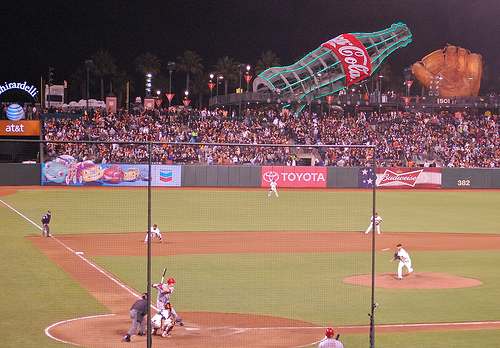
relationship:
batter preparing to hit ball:
[151, 270, 186, 300] [378, 245, 389, 257]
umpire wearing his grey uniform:
[126, 290, 148, 340] [130, 306, 144, 322]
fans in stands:
[87, 116, 123, 144] [114, 130, 229, 172]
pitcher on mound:
[389, 243, 416, 270] [377, 267, 417, 299]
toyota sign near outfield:
[262, 166, 324, 185] [223, 187, 318, 222]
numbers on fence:
[456, 178, 472, 190] [446, 170, 496, 189]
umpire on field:
[126, 290, 148, 340] [206, 269, 256, 299]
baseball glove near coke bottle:
[417, 42, 489, 104] [253, 29, 402, 91]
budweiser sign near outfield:
[364, 167, 442, 187] [223, 187, 318, 222]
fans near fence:
[87, 116, 123, 144] [446, 170, 496, 189]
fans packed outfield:
[87, 116, 123, 144] [223, 187, 318, 222]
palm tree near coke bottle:
[135, 49, 161, 84] [253, 29, 402, 91]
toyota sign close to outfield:
[262, 166, 324, 185] [223, 187, 318, 222]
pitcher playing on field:
[389, 243, 416, 270] [206, 269, 256, 299]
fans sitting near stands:
[87, 116, 123, 144] [114, 130, 229, 172]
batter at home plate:
[151, 270, 186, 300] [181, 319, 200, 335]